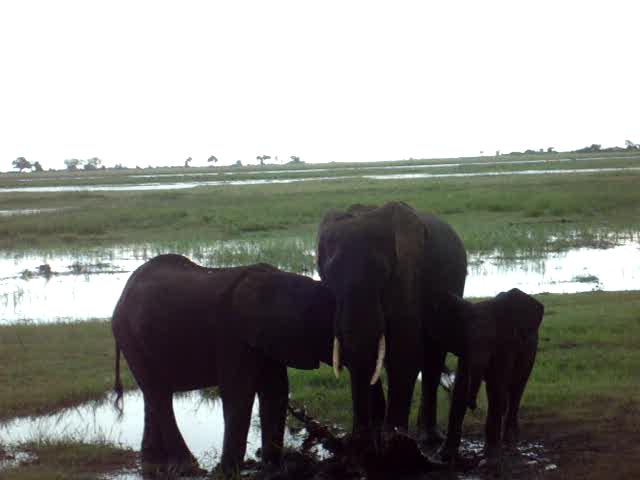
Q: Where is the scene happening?
A: In a swamp.